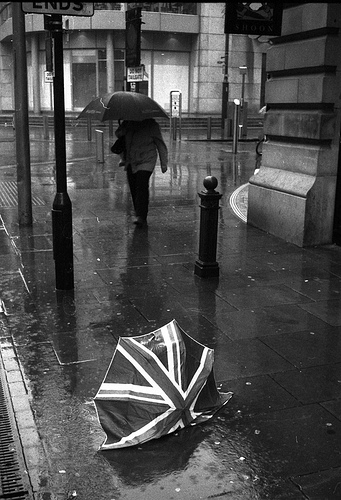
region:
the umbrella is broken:
[62, 313, 297, 493]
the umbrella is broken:
[91, 317, 230, 448]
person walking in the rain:
[84, 90, 169, 221]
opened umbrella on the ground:
[92, 319, 236, 444]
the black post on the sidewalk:
[195, 174, 222, 278]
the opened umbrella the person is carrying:
[75, 90, 170, 117]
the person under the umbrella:
[112, 119, 167, 228]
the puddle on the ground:
[56, 450, 216, 497]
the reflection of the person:
[82, 226, 170, 329]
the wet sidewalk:
[233, 259, 339, 397]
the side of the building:
[245, 41, 339, 240]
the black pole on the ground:
[52, 14, 76, 292]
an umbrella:
[102, 345, 201, 466]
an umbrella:
[114, 346, 167, 456]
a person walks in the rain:
[71, 83, 184, 231]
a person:
[76, 82, 179, 230]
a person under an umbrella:
[79, 82, 175, 236]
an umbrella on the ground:
[84, 303, 241, 451]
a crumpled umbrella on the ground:
[89, 315, 242, 455]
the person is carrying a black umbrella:
[72, 81, 177, 231]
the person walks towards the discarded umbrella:
[27, 68, 246, 442]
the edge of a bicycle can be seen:
[253, 95, 271, 168]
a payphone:
[167, 87, 185, 142]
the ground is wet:
[5, 140, 326, 497]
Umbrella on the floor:
[92, 315, 241, 454]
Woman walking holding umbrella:
[74, 87, 174, 232]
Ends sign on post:
[8, 1, 103, 37]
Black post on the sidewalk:
[35, 22, 78, 292]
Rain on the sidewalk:
[2, 191, 50, 342]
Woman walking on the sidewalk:
[78, 87, 175, 231]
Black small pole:
[184, 170, 230, 281]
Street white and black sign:
[116, 57, 152, 84]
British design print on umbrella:
[87, 313, 237, 454]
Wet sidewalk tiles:
[1, 298, 93, 430]